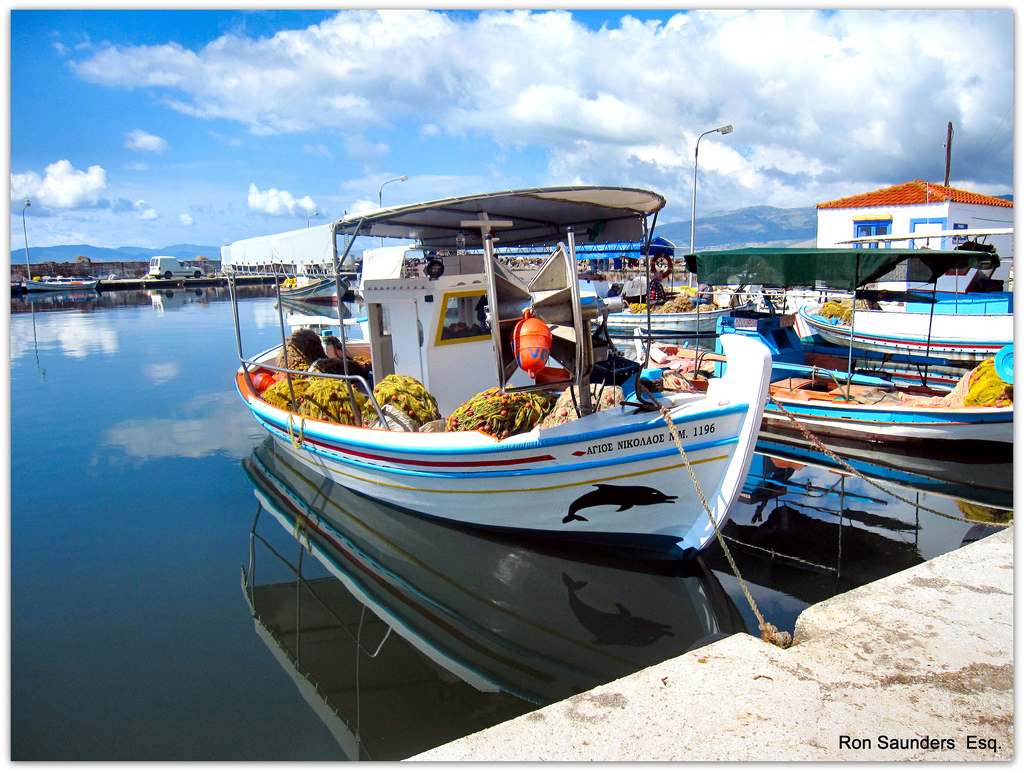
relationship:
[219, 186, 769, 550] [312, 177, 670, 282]
boat has canopy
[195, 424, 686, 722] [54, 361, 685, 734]
reflection on water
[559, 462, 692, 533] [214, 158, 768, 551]
picture on boat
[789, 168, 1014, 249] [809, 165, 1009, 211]
building with roof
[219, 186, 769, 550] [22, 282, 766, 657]
boat in water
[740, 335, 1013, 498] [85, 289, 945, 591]
boat on water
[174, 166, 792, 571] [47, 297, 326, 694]
boat on water